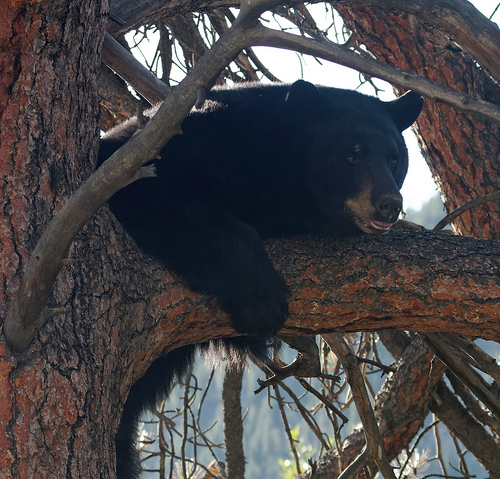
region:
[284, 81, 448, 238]
The bears face is black.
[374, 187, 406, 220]
The bears nose is black.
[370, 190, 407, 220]
The bears nose is large.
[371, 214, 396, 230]
The bears tongue is black.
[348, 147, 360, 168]
The bears right eye is black.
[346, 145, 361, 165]
The bears right eye is small.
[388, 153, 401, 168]
The bears left eye is black.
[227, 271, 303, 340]
The bears paw is large.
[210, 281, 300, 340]
The bears paw is black.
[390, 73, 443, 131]
ear of the bear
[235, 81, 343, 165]
black fur on the bear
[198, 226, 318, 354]
paw of the bear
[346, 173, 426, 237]
nose of the bear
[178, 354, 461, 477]
branches under the tree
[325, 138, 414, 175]
two eyes of the bear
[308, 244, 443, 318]
branch under the bear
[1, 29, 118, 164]
tree in the photo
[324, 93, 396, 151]
top of the bear's head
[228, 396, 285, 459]
blurry background of photo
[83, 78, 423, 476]
Bear hanging on a tree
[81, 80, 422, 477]
Bear resting on a thick tree branch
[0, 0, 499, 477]
Large brown tree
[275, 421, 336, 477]
Green leaves of a plant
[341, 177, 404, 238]
Brown mouth of a bear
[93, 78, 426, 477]
Black bear resting on a tree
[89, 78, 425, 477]
Black bear climbing a tree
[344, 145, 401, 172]
Pair of small black bear eyes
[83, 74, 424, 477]
Black bear with his arm around a tree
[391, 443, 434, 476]
Two white petal flowers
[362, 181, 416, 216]
nose of the bear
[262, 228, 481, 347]
branch under the bear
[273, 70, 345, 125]
ear of the bear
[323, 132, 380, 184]
eye of the animal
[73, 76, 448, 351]
one bear in the tree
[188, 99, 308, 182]
black fur on the bear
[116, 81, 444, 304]
black bear in the tree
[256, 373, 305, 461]
branch of the tree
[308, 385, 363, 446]
branch of the tree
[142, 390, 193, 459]
branch of the tree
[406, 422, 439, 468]
branch of the tree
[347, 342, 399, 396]
branch of the tree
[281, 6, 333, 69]
branch of the tree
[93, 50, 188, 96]
branch of the tree